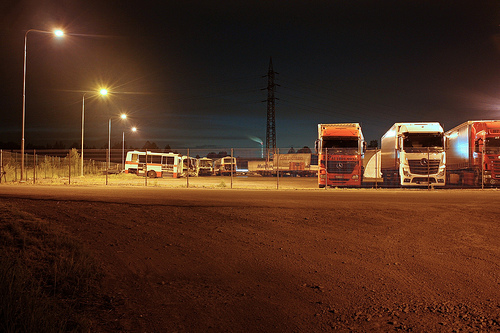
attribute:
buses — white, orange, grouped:
[305, 113, 380, 198]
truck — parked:
[438, 116, 498, 188]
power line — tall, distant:
[261, 51, 281, 156]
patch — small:
[3, 232, 110, 331]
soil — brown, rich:
[0, 181, 500, 331]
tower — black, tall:
[259, 49, 285, 161]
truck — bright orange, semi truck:
[317, 122, 365, 185]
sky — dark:
[3, 3, 498, 155]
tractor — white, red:
[310, 117, 364, 184]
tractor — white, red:
[380, 112, 446, 192]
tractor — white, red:
[444, 117, 497, 185]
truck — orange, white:
[318, 125, 363, 186]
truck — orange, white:
[378, 127, 440, 181]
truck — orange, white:
[441, 130, 495, 182]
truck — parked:
[313, 121, 363, 191]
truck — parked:
[310, 109, 372, 223]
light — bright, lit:
[50, 26, 69, 40]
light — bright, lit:
[95, 84, 111, 101]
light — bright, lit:
[120, 110, 128, 120]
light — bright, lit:
[130, 122, 138, 133]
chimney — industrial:
[264, 50, 276, 162]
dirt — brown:
[195, 223, 253, 288]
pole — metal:
[263, 101, 276, 152]